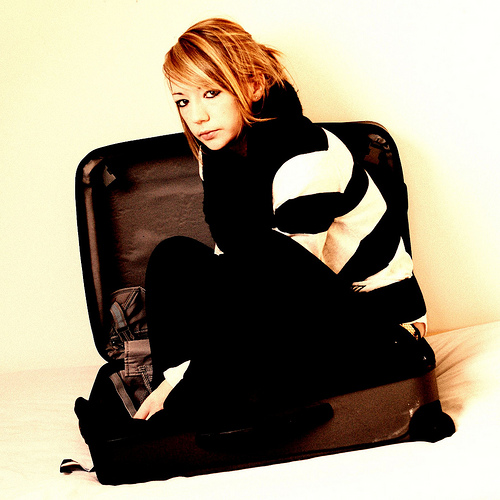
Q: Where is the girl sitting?
A: Suitcase.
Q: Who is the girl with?
A: No one.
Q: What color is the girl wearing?
A: Black and white.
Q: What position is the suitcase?
A: Open.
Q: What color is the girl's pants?
A: Black.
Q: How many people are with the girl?
A: None.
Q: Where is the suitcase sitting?
A: Bed.